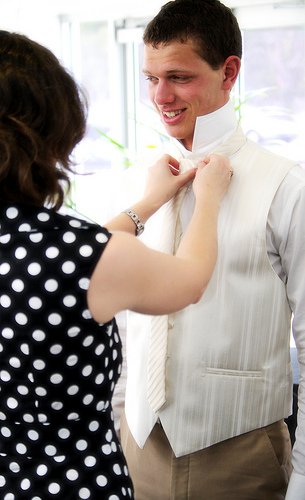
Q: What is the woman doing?
A: Tying the man's tie.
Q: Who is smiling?
A: The young man.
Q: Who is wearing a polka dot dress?
A: The woman.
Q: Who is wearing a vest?
A: The young man.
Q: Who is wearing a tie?
A: The young man.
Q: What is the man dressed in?
A: A white shirt.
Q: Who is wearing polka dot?
A: The woman.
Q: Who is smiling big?
A: The man.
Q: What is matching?
A: The vest and tie.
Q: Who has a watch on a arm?
A: The woman.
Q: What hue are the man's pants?
A: Khaki.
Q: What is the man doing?
A: Smiling.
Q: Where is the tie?
A: Around the man's neck.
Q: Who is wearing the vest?
A: The man.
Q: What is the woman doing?
A: Tying man's tie.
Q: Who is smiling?
A: The man.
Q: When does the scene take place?
A: During daytime.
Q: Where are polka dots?
A: On woman's dress.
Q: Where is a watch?
A: Around woman's left wrist.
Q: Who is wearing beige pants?
A: The guy.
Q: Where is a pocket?
A: On white vest.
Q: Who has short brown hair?
A: A man.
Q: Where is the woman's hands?
A: On man's tie.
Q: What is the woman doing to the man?
A: She is tying his tie.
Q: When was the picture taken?
A: Daytime.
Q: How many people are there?
A: Two.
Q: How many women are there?
A: One.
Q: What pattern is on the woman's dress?
A: Polka dots.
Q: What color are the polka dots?
A: White.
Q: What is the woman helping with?
A: A tie.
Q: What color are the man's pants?
A: Beige.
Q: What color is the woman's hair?
A: Brown.